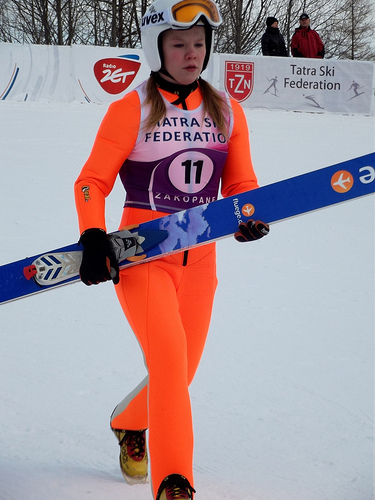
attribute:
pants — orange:
[111, 227, 231, 488]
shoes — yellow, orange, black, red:
[108, 418, 202, 499]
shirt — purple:
[114, 83, 238, 212]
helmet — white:
[135, 0, 229, 75]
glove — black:
[74, 225, 125, 289]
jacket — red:
[291, 24, 325, 55]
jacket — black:
[259, 27, 288, 55]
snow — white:
[2, 100, 371, 495]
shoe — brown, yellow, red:
[110, 418, 152, 480]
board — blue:
[1, 148, 373, 296]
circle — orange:
[329, 166, 354, 196]